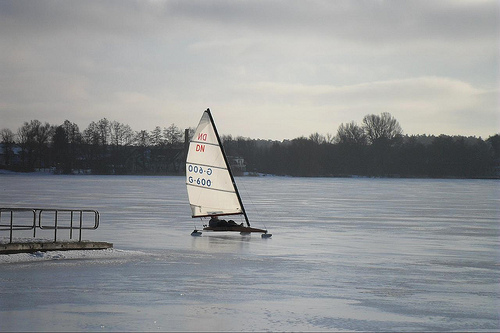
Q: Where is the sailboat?
A: On the water.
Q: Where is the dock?
A: To the left of the boat.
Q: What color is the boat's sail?
A: White.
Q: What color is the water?
A: Grey.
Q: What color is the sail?
A: White.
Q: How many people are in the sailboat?
A: 1.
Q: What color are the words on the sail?
A: Blue and white.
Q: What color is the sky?
A: Grey.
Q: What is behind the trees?
A: A building.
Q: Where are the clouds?
A: In the sky.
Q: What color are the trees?
A: Black.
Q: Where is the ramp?
A: On the left side of the picture.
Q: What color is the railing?
A: Grey.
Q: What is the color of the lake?
A: Pale blue.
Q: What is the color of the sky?
A: Gray.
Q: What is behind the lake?
A: Trees.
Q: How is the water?
A: Calm.